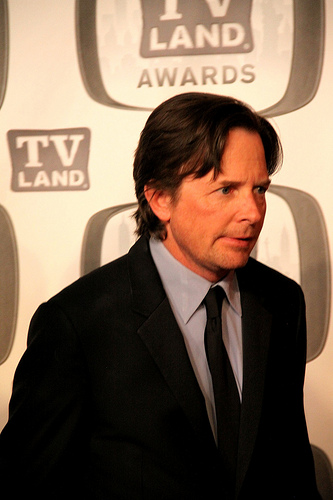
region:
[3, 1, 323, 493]
photo taken during TV land awards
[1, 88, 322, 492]
man wearing black suit and tie with light lbue shirt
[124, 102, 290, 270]
head of man with medium length dark brown hair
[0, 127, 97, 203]
TV LAND logo in gray on a tan wall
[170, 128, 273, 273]
face of man with medium length brown hair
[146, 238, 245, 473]
black tie and light blue shirt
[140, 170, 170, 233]
ear of man with medium length dark brown hair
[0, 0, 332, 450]
tan wall with gray logos on it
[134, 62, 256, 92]
gray lettering spelling awards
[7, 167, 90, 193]
white lettering spelling land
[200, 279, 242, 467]
black necktie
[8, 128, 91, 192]
logo in the background for TV Land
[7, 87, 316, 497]
Michael J. Fox looking to the side of the camera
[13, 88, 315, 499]
Michael J. Fox wearing a black suit and tie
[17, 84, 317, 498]
Michael J. Fox wearing a black suit and blue shirt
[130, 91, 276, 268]
man with brown hair and blue eyes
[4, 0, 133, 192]
gray and white background for the TV Land Awards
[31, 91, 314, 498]
man wearing a blue shirt and a black suit jacket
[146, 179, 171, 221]
Michael J. Fox's ear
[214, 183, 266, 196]
Michael J. Fox's eyes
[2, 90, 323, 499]
man in a black suit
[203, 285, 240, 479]
black tie on a man's suit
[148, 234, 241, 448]
gray shirt wore by a man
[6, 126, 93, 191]
black logo of TV Land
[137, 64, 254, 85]
black letters saying Awards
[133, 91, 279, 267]
head of a man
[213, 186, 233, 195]
open right eye of a man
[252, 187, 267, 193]
open left eye of a man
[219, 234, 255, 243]
closed mouth of a man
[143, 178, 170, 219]
right ear of a man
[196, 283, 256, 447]
black tie on neck of person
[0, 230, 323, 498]
black suit jacket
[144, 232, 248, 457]
grey collared shirt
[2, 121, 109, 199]
black and white sign on wall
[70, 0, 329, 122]
large balck and white sign on wall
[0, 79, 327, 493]
man in suit jacket walking past signs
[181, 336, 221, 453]
black shadow on shirt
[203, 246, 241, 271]
chin stubble on person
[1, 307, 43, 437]
crease marks on jacket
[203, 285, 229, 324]
knot at top of black tie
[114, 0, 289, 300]
Michael J Fox at the TV Land Awards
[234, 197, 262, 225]
the nose of a man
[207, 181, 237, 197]
the eye of a man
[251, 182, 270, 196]
the eye of a man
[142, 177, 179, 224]
the ear of a man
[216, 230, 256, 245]
the mouth of a man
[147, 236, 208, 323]
the collar of a dress shirt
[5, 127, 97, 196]
a TV Land logo on the wall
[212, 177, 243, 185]
the eyebrow of a man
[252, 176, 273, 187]
the eyebrow of a man